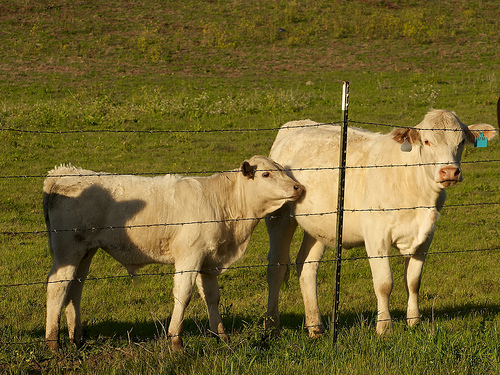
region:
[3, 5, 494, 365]
green grass of field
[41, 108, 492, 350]
two cows standing on grass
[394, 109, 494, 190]
head of cow with tags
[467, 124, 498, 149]
blue tag in ear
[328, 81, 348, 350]
metal pole in grass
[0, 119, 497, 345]
barbed wire of fence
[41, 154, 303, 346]
side of white cow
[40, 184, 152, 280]
shadow on cow body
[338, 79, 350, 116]
silver top of fence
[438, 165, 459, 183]
nose on cow's face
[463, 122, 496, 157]
a blue tag on ear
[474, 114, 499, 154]
a blue tag on ear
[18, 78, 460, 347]
two cows behind the fence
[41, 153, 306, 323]
A white small cow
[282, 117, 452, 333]
A white big cow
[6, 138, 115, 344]
A silver barbed wire fance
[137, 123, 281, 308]
A silver barbed wire fance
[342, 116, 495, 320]
A silver barbed wire fance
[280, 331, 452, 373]
A thick green grass field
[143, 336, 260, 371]
A thick green grass field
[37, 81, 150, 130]
A thick green grass field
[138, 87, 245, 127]
A thick green grass field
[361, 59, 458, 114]
A thick green grass field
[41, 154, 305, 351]
a cow in a field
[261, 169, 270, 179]
eye of a cow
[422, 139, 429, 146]
eye of a cow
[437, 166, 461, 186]
mouth and nose of a cow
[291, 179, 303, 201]
mouth and nose of a cow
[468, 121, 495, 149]
tagged ear of a cow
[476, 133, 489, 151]
a small blue tag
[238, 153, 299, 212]
head of a cow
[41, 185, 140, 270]
shadow of a cow's head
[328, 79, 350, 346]
green and white metal post